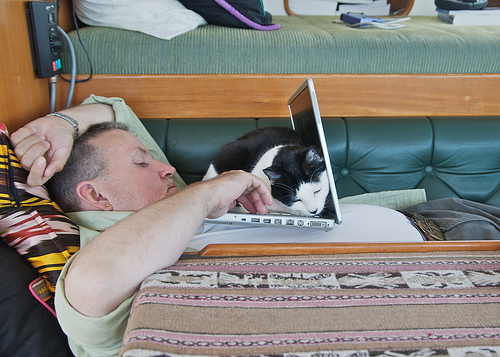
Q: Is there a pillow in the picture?
A: Yes, there is a pillow.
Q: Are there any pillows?
A: Yes, there is a pillow.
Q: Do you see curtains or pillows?
A: Yes, there is a pillow.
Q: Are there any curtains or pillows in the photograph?
A: Yes, there is a pillow.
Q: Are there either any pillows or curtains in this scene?
A: Yes, there is a pillow.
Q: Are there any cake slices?
A: No, there are no cake slices.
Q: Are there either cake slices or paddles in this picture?
A: No, there are no cake slices or paddles.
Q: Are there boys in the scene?
A: No, there are no boys.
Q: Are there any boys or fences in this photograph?
A: No, there are no boys or fences.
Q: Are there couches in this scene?
A: Yes, there is a couch.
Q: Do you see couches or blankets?
A: Yes, there is a couch.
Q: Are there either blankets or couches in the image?
A: Yes, there is a couch.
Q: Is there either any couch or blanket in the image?
A: Yes, there is a couch.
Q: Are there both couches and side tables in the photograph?
A: No, there is a couch but no side tables.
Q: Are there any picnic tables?
A: No, there are no picnic tables.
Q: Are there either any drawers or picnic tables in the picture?
A: No, there are no picnic tables or drawers.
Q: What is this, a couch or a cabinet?
A: This is a couch.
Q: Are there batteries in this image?
A: No, there are no batteries.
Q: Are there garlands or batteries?
A: No, there are no batteries or garlands.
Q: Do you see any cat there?
A: Yes, there is a cat.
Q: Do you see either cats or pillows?
A: Yes, there is a cat.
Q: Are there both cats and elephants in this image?
A: No, there is a cat but no elephants.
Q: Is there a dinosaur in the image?
A: No, there are no dinosaurs.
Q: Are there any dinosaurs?
A: No, there are no dinosaurs.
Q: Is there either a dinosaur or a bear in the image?
A: No, there are no dinosaurs or bears.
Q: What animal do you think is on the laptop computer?
A: The cat is on the laptop computer.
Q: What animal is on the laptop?
A: The cat is on the laptop computer.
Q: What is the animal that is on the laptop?
A: The animal is a cat.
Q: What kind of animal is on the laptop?
A: The animal is a cat.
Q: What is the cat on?
A: The cat is on the laptop computer.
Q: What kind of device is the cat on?
A: The cat is on the laptop.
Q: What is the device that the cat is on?
A: The device is a laptop.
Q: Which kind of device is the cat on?
A: The cat is on the laptop.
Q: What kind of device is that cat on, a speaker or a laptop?
A: The cat is on a laptop.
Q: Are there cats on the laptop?
A: Yes, there is a cat on the laptop.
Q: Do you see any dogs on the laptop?
A: No, there is a cat on the laptop.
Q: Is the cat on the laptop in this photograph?
A: Yes, the cat is on the laptop.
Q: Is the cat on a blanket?
A: No, the cat is on the laptop.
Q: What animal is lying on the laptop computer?
A: The cat is lying on the laptop computer.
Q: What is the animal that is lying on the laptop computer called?
A: The animal is a cat.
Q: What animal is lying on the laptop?
A: The animal is a cat.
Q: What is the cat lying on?
A: The cat is lying on the laptop.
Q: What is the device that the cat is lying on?
A: The device is a laptop.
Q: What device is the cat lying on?
A: The cat is lying on the laptop.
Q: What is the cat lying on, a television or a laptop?
A: The cat is lying on a laptop.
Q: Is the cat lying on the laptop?
A: Yes, the cat is lying on the laptop.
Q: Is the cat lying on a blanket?
A: No, the cat is lying on the laptop.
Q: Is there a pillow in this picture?
A: Yes, there is a pillow.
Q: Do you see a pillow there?
A: Yes, there is a pillow.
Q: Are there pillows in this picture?
A: Yes, there is a pillow.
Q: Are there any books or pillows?
A: Yes, there is a pillow.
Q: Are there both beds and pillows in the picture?
A: Yes, there are both a pillow and a bed.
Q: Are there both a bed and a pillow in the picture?
A: Yes, there are both a pillow and a bed.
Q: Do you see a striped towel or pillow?
A: Yes, there is a striped pillow.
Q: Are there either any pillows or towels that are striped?
A: Yes, the pillow is striped.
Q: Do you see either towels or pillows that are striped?
A: Yes, the pillow is striped.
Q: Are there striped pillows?
A: Yes, there is a striped pillow.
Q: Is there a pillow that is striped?
A: Yes, there is a pillow that is striped.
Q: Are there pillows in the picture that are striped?
A: Yes, there is a pillow that is striped.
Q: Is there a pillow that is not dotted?
A: Yes, there is a striped pillow.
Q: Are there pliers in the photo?
A: No, there are no pliers.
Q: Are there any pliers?
A: No, there are no pliers.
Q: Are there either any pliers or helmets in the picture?
A: No, there are no pliers or helmets.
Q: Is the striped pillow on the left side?
A: Yes, the pillow is on the left of the image.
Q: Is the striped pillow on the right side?
A: No, the pillow is on the left of the image.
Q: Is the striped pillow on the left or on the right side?
A: The pillow is on the left of the image.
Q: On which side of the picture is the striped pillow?
A: The pillow is on the left of the image.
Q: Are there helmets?
A: No, there are no helmets.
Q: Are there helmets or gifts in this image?
A: No, there are no helmets or gifts.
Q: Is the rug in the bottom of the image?
A: Yes, the rug is in the bottom of the image.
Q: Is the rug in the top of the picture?
A: No, the rug is in the bottom of the image.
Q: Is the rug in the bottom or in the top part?
A: The rug is in the bottom of the image.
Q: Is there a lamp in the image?
A: No, there are no lamps.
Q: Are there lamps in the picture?
A: No, there are no lamps.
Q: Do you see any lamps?
A: No, there are no lamps.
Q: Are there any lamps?
A: No, there are no lamps.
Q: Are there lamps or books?
A: No, there are no lamps or books.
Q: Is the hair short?
A: Yes, the hair is short.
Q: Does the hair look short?
A: Yes, the hair is short.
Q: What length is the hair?
A: The hair is short.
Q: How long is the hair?
A: The hair is short.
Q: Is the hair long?
A: No, the hair is short.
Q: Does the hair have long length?
A: No, the hair is short.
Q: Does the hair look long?
A: No, the hair is short.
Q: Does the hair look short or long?
A: The hair is short.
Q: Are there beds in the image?
A: Yes, there is a bed.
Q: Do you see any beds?
A: Yes, there is a bed.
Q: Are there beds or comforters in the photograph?
A: Yes, there is a bed.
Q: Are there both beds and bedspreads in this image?
A: No, there is a bed but no bedspreads.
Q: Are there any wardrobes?
A: No, there are no wardrobes.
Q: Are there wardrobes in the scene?
A: No, there are no wardrobes.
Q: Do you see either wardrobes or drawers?
A: No, there are no wardrobes or drawers.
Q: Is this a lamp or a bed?
A: This is a bed.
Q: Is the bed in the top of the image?
A: Yes, the bed is in the top of the image.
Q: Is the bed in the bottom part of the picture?
A: No, the bed is in the top of the image.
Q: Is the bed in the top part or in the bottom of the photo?
A: The bed is in the top of the image.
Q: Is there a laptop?
A: Yes, there is a laptop.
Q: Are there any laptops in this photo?
A: Yes, there is a laptop.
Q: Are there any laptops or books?
A: Yes, there is a laptop.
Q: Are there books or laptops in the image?
A: Yes, there is a laptop.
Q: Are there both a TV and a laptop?
A: No, there is a laptop but no televisions.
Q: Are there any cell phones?
A: No, there are no cell phones.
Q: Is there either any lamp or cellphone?
A: No, there are no cell phones or lamps.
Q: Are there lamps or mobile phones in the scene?
A: No, there are no mobile phones or lamps.